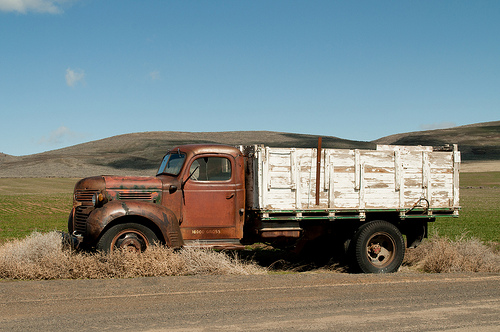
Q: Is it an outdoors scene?
A: Yes, it is outdoors.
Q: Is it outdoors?
A: Yes, it is outdoors.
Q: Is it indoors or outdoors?
A: It is outdoors.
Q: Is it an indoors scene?
A: No, it is outdoors.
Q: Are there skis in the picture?
A: No, there are no skis.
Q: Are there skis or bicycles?
A: No, there are no skis or bicycles.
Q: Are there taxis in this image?
A: Yes, there is a taxi.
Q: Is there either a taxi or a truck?
A: Yes, there is a taxi.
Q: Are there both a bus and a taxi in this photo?
A: No, there is a taxi but no buses.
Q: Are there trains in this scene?
A: No, there are no trains.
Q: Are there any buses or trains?
A: No, there are no trains or buses.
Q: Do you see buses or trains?
A: No, there are no trains or buses.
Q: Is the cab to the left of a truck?
A: Yes, the cab is to the left of a truck.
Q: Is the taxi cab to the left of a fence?
A: No, the taxi cab is to the left of a truck.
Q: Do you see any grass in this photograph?
A: Yes, there is grass.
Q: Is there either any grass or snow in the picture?
A: Yes, there is grass.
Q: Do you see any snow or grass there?
A: Yes, there is grass.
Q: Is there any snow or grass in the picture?
A: Yes, there is grass.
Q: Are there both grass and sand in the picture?
A: No, there is grass but no sand.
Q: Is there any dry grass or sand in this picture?
A: Yes, there is dry grass.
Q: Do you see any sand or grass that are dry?
A: Yes, the grass is dry.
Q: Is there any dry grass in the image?
A: Yes, there is dry grass.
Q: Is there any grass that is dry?
A: Yes, there is dry grass.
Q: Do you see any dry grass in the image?
A: Yes, there is dry grass.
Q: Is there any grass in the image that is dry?
A: Yes, there is grass that is dry.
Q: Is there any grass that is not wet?
A: Yes, there is dry grass.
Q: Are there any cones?
A: No, there are no cones.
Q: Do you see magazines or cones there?
A: No, there are no cones or magazines.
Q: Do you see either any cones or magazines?
A: No, there are no cones or magazines.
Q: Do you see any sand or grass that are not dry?
A: No, there is grass but it is dry.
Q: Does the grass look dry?
A: Yes, the grass is dry.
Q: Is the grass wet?
A: No, the grass is dry.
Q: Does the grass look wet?
A: No, the grass is dry.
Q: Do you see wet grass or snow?
A: No, there is grass but it is dry.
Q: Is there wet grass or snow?
A: No, there is grass but it is dry.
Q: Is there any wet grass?
A: No, there is grass but it is dry.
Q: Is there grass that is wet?
A: No, there is grass but it is dry.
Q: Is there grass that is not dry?
A: No, there is grass but it is dry.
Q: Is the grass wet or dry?
A: The grass is dry.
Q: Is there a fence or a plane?
A: No, there are no fences or airplanes.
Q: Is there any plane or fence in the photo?
A: No, there are no fences or airplanes.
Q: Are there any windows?
A: Yes, there is a window.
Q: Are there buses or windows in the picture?
A: Yes, there is a window.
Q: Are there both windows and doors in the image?
A: Yes, there are both a window and a door.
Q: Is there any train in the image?
A: No, there are no trains.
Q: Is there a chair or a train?
A: No, there are no trains or chairs.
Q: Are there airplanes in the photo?
A: No, there are no airplanes.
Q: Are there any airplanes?
A: No, there are no airplanes.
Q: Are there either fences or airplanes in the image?
A: No, there are no airplanes or fences.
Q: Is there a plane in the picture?
A: No, there are no airplanes.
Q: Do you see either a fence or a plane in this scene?
A: No, there are no airplanes or fences.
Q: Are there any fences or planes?
A: No, there are no planes or fences.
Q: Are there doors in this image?
A: Yes, there is a door.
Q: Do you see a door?
A: Yes, there is a door.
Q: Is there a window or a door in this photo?
A: Yes, there is a door.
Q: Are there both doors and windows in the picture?
A: Yes, there are both a door and a window.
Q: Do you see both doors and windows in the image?
A: Yes, there are both a door and a window.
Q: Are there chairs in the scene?
A: No, there are no chairs.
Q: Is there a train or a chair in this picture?
A: No, there are no chairs or trains.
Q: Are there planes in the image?
A: No, there are no planes.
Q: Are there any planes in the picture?
A: No, there are no planes.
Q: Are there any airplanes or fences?
A: No, there are no airplanes or fences.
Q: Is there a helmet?
A: No, there are no helmets.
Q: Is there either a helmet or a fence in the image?
A: No, there are no helmets or fences.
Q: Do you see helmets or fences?
A: No, there are no helmets or fences.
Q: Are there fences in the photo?
A: No, there are no fences.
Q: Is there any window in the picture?
A: Yes, there is a window.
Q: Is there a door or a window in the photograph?
A: Yes, there is a window.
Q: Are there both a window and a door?
A: Yes, there are both a window and a door.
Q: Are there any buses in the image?
A: No, there are no buses.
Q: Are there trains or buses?
A: No, there are no buses or trains.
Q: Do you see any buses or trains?
A: No, there are no buses or trains.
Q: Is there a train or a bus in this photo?
A: No, there are no buses or trains.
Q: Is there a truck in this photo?
A: Yes, there is a truck.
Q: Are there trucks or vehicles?
A: Yes, there is a truck.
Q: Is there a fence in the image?
A: No, there are no fences.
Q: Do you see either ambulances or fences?
A: No, there are no fences or ambulances.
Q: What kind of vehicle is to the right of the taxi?
A: The vehicle is a truck.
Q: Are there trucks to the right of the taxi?
A: Yes, there is a truck to the right of the taxi.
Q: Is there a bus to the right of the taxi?
A: No, there is a truck to the right of the taxi.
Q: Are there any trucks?
A: Yes, there is a truck.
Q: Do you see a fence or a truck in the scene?
A: Yes, there is a truck.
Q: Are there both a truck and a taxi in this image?
A: Yes, there are both a truck and a taxi.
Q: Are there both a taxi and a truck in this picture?
A: Yes, there are both a truck and a taxi.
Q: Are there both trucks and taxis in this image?
A: Yes, there are both a truck and a taxi.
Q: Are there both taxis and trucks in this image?
A: Yes, there are both a truck and a taxi.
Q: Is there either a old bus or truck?
A: Yes, there is an old truck.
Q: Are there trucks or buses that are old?
A: Yes, the truck is old.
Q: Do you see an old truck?
A: Yes, there is an old truck.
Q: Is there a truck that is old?
A: Yes, there is a truck that is old.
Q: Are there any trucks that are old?
A: Yes, there is a truck that is old.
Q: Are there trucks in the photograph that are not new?
A: Yes, there is a old truck.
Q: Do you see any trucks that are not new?
A: Yes, there is a old truck.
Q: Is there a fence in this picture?
A: No, there are no fences.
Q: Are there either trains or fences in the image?
A: No, there are no fences or trains.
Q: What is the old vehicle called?
A: The vehicle is a truck.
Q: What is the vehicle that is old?
A: The vehicle is a truck.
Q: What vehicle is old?
A: The vehicle is a truck.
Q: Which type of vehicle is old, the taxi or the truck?
A: The truck is old.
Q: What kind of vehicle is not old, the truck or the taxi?
A: The taxi is not old.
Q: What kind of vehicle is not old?
A: The vehicle is a taxi.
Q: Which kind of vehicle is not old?
A: The vehicle is a taxi.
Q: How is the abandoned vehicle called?
A: The vehicle is a truck.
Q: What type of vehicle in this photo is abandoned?
A: The vehicle is a truck.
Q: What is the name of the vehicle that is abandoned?
A: The vehicle is a truck.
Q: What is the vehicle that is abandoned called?
A: The vehicle is a truck.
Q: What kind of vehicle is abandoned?
A: The vehicle is a truck.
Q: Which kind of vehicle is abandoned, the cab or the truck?
A: The truck is abandoned.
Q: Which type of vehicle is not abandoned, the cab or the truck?
A: The cab is not abandoned.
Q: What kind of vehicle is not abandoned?
A: The vehicle is a taxi.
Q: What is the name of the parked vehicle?
A: The vehicle is a truck.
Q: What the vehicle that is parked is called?
A: The vehicle is a truck.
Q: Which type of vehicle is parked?
A: The vehicle is a truck.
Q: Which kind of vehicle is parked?
A: The vehicle is a truck.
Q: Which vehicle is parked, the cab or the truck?
A: The truck is parked.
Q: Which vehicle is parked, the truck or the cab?
A: The truck is parked.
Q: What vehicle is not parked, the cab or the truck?
A: The cab is not parked.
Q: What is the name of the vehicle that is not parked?
A: The vehicle is a taxi.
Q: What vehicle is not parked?
A: The vehicle is a taxi.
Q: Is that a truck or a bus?
A: That is a truck.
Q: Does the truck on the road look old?
A: Yes, the truck is old.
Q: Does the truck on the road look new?
A: No, the truck is old.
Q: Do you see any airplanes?
A: No, there are no airplanes.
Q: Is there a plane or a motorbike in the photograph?
A: No, there are no airplanes or motorcycles.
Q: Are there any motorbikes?
A: No, there are no motorbikes.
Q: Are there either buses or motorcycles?
A: No, there are no motorcycles or buses.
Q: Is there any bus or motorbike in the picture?
A: No, there are no motorcycles or buses.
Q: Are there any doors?
A: Yes, there is a door.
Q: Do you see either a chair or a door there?
A: Yes, there is a door.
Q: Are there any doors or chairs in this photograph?
A: Yes, there is a door.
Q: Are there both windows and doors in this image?
A: Yes, there are both a door and a window.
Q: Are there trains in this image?
A: No, there are no trains.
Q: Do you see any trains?
A: No, there are no trains.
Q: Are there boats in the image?
A: No, there are no boats.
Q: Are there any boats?
A: No, there are no boats.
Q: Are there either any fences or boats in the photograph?
A: No, there are no boats or fences.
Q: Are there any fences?
A: No, there are no fences.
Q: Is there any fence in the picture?
A: No, there are no fences.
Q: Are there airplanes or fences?
A: No, there are no fences or airplanes.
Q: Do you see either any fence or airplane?
A: No, there are no fences or airplanes.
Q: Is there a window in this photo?
A: Yes, there is a window.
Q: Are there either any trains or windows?
A: Yes, there is a window.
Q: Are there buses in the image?
A: No, there are no buses.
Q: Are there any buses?
A: No, there are no buses.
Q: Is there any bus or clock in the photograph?
A: No, there are no buses or clocks.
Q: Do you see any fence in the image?
A: No, there are no fences.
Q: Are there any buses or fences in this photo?
A: No, there are no fences or buses.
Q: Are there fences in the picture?
A: No, there are no fences.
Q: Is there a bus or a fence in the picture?
A: No, there are no fences or buses.